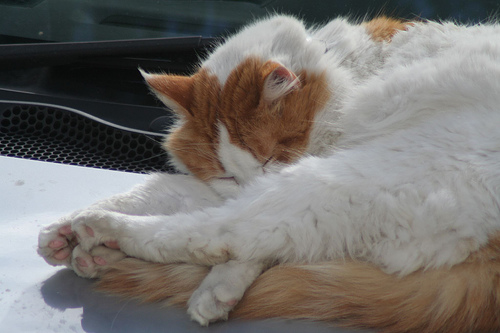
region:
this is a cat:
[140, 20, 480, 299]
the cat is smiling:
[35, 17, 499, 329]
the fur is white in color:
[356, 68, 476, 192]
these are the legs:
[28, 204, 143, 271]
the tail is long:
[261, 272, 398, 317]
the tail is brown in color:
[273, 262, 364, 310]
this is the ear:
[256, 62, 291, 94]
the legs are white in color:
[37, 208, 127, 270]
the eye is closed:
[257, 145, 282, 162]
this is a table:
[41, 162, 81, 207]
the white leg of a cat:
[72, 148, 377, 263]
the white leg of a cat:
[186, 251, 263, 320]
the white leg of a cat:
[42, 165, 211, 265]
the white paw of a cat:
[79, 207, 145, 264]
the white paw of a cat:
[33, 218, 81, 263]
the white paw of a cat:
[65, 241, 127, 278]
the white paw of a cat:
[185, 264, 261, 325]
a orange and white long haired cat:
[30, 18, 497, 323]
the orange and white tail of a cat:
[103, 247, 498, 332]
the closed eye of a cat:
[212, 167, 240, 189]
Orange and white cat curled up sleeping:
[26, 9, 496, 331]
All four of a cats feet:
[27, 201, 249, 331]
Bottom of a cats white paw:
[36, 216, 76, 272]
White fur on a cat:
[320, 170, 445, 225]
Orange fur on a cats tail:
[80, 242, 490, 327]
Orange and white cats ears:
[125, 50, 310, 125]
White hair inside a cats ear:
[265, 75, 287, 95]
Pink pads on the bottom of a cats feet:
[47, 232, 64, 259]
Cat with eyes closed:
[140, 56, 327, 208]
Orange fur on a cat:
[192, 91, 250, 111]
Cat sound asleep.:
[36, 9, 493, 331]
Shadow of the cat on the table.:
[37, 259, 312, 331]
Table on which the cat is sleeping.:
[1, 146, 356, 331]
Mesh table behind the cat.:
[6, 39, 207, 173]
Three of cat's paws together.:
[38, 210, 140, 275]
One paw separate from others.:
[184, 260, 273, 325]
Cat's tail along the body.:
[100, 250, 498, 328]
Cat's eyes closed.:
[203, 143, 285, 188]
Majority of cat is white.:
[39, 11, 499, 328]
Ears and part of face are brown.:
[136, 62, 326, 178]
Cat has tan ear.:
[144, 62, 190, 114]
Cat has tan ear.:
[242, 60, 290, 97]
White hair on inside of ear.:
[268, 79, 310, 104]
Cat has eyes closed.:
[216, 140, 284, 203]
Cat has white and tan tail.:
[282, 260, 373, 329]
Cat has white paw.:
[178, 270, 233, 317]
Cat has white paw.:
[92, 202, 143, 256]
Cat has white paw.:
[63, 249, 138, 291]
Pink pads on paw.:
[41, 222, 96, 273]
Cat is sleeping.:
[147, 110, 398, 330]